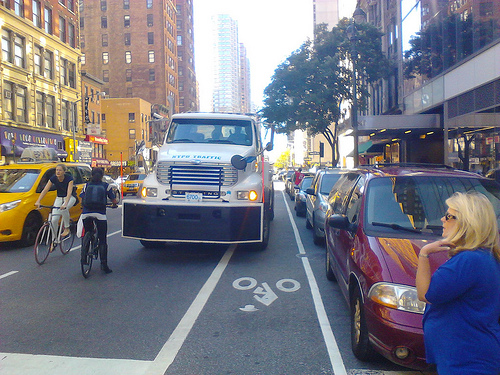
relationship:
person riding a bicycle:
[79, 160, 111, 217] [78, 212, 102, 272]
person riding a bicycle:
[41, 157, 74, 232] [28, 194, 79, 267]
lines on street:
[157, 245, 341, 372] [1, 188, 340, 373]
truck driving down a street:
[121, 111, 274, 248] [0, 173, 387, 373]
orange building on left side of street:
[101, 97, 153, 162] [103, 152, 283, 369]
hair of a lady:
[440, 185, 495, 254] [416, 190, 500, 374]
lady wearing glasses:
[416, 190, 500, 374] [446, 212, 460, 221]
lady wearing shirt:
[416, 190, 500, 374] [406, 240, 499, 372]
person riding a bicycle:
[35, 164, 77, 253] [34, 205, 77, 265]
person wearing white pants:
[35, 164, 77, 253] [43, 190, 76, 240]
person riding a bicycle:
[76, 167, 119, 274] [80, 217, 100, 279]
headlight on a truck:
[241, 182, 259, 204] [121, 111, 274, 248]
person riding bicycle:
[76, 167, 119, 274] [76, 217, 101, 282]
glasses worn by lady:
[441, 210, 460, 224] [414, 189, 497, 374]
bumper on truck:
[119, 197, 267, 248] [83, 59, 337, 279]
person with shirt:
[290, 162, 304, 192] [291, 170, 302, 187]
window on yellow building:
[29, 39, 45, 76] [1, 3, 93, 146]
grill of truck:
[154, 159, 236, 198] [121, 111, 274, 248]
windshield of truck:
[165, 116, 252, 143] [118, 108, 276, 259]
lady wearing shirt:
[416, 190, 500, 374] [418, 248, 498, 372]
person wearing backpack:
[76, 167, 119, 274] [80, 180, 108, 210]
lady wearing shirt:
[416, 190, 500, 374] [415, 257, 492, 368]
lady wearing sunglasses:
[416, 190, 500, 374] [437, 212, 463, 222]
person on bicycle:
[76, 167, 119, 274] [77, 216, 97, 276]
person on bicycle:
[35, 164, 77, 253] [31, 200, 76, 267]